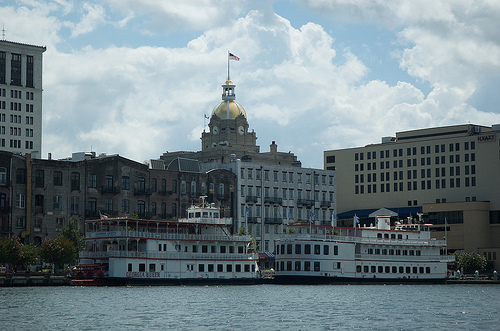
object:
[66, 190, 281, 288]
boat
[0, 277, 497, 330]
water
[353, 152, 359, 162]
window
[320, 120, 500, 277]
building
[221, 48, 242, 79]
flag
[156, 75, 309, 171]
building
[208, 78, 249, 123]
dome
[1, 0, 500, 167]
sky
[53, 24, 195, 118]
cloud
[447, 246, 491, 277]
bush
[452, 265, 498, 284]
shorte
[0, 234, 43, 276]
tree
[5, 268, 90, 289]
shore